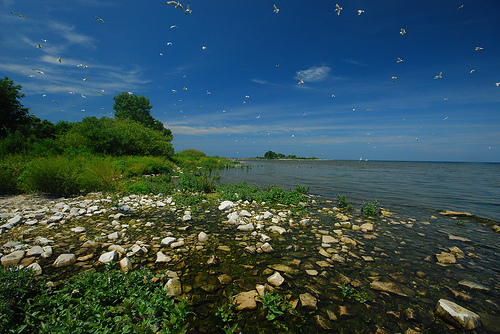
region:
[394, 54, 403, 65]
A bird flying in the sky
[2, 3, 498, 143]
A cluster of birds flying in the sky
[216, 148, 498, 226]
A body of water next to some green scenery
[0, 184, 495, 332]
A group of rocks sticking out from the water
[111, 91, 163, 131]
The top of a tree next to the water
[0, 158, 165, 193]
Green bush near the rocks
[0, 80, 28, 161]
A bushy tree on a green piece of land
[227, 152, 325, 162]
A green island far out in the water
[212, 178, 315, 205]
Some green plants coming up from the water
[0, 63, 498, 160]
The blue sky above the water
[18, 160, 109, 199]
plants on a coast line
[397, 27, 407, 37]
bird in the clear sky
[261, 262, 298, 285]
rocks in the clear water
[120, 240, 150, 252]
rocks in the clear water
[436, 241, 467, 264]
rocks in the clear water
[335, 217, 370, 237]
rocks in the clear water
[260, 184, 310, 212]
palnts and rock in water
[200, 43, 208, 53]
bird in the clear sky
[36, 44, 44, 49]
bird in the clear sky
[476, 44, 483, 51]
bird in the clear sky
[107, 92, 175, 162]
this is an old tree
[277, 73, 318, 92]
this is a cloud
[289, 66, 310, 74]
the cloud is white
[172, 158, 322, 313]
these are some wet rocks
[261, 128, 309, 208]
this is the ocean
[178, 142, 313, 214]
there are no people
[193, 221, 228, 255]
there are no animals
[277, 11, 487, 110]
these are some birds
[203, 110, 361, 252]
the birds are white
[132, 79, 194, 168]
the trees are very dark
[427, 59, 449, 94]
the bird is flying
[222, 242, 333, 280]
the rocks are in the water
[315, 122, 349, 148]
the cloud is thin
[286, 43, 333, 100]
the cloud is in the sky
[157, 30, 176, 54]
the bird is in the sky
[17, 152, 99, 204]
the bush is small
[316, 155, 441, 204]
the water is dark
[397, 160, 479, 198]
the water is calm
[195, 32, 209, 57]
the bird is white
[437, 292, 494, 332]
the rock is gray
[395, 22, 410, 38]
a bird flying in the sky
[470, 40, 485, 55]
a bird flying in the sky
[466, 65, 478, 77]
a bird flying in the sky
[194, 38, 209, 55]
a bird flying in the sky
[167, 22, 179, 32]
a bird flying in the sky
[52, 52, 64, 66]
a bird flying in the sky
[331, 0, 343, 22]
a bird flying in the sky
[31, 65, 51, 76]
a bird flying in the sky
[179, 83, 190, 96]
a bird flying in the sky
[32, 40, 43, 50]
a bird flying in the sky